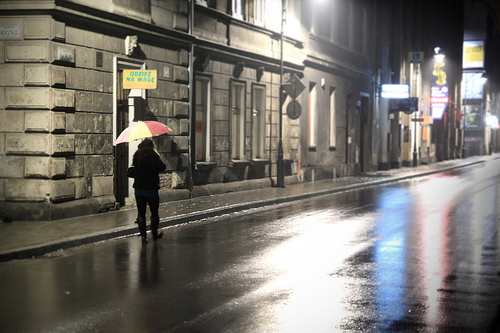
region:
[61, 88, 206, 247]
This is a person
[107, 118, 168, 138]
This umbrella is multicolored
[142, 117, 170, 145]
Part of the umbrellas is red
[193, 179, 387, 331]
The ground is wet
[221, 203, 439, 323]
The ground here is shiny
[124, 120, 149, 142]
This part of the umbrella is yellow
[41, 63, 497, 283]
The weather is rainy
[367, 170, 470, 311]
The reflections are blue and red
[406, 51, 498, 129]
These signs are lit up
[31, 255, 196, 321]
The ground is made of concrete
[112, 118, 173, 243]
woman carrying red and yellow umbrella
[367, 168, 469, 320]
reflection of neon lights on wet street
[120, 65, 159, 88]
yellow sign with green writing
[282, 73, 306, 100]
grey back of triangular sign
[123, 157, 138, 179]
black handbag on woman's shoulder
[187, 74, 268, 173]
windows on side of building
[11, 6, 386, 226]
tan concrete building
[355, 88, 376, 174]
entrance door to building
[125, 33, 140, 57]
lion statue onside of building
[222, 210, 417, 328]
dark wet street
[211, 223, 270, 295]
the pavement is wet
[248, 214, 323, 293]
the pavement is wet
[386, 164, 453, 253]
the pavement is wet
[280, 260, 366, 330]
the pavement is wet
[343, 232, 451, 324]
the pavement is wet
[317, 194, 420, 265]
the pavement is wet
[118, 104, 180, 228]
a woman with umbrella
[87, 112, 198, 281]
a woman with umbrella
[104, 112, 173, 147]
red and yellow umbrella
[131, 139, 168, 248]
person dressed in dark clothing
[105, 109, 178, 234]
person and umbrella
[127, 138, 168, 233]
person carrying umbrella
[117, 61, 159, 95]
green and yellow sign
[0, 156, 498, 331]
wet street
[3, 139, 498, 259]
sidewalk being splattered with rain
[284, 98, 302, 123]
back of a circle sign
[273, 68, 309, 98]
back of a four sided sign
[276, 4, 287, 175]
pole the back sign are on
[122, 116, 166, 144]
an umbrella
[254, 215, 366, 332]
reflection of light on the street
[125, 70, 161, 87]
a sign on the building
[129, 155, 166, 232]
a person walking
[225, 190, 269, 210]
the sidewalk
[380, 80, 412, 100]
a sign with lights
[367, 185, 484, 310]
the street is black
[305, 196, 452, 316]
the street is wet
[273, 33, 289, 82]
a pole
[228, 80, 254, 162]
a door